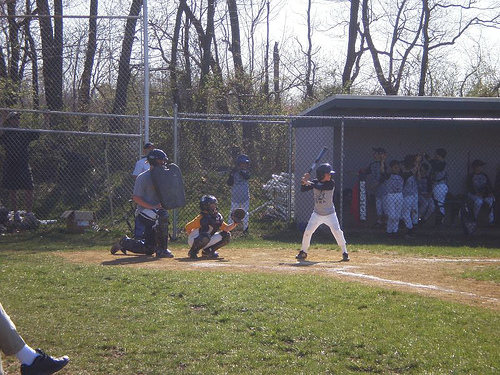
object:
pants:
[298, 211, 348, 256]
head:
[313, 163, 336, 183]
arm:
[307, 177, 334, 192]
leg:
[325, 213, 348, 254]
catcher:
[185, 193, 247, 258]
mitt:
[229, 207, 244, 223]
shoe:
[18, 348, 69, 374]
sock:
[14, 343, 41, 370]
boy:
[293, 159, 349, 262]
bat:
[314, 164, 337, 177]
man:
[0, 103, 49, 229]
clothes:
[0, 125, 44, 194]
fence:
[9, 14, 139, 238]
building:
[291, 93, 499, 236]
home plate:
[308, 257, 343, 269]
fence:
[2, 110, 499, 239]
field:
[0, 233, 498, 374]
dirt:
[38, 240, 498, 313]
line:
[332, 266, 499, 305]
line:
[336, 254, 497, 269]